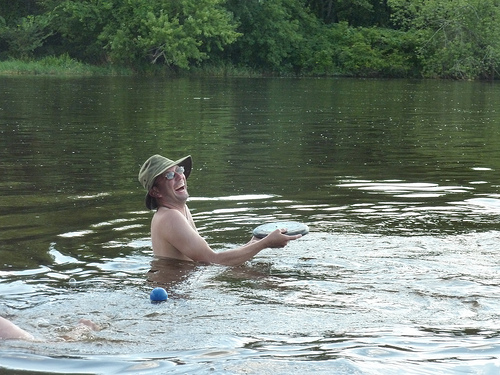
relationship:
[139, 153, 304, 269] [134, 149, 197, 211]
fair-skinned man wearing a hat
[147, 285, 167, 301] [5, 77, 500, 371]
ball in water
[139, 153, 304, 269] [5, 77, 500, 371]
fair-skinned man in water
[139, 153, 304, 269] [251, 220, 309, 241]
fair-skinned man holds frisbee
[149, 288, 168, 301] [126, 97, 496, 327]
ball floating on water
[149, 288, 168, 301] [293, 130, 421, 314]
ball floating on water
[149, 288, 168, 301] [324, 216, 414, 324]
ball floating on water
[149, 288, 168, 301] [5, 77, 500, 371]
ball floating on water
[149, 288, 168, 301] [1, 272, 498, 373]
ball floating on water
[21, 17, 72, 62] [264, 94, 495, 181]
trees beside water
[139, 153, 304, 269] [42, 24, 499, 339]
fair-skinned man in water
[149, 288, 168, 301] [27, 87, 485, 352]
ball floats on water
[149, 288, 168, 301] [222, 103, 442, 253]
ball floats on water